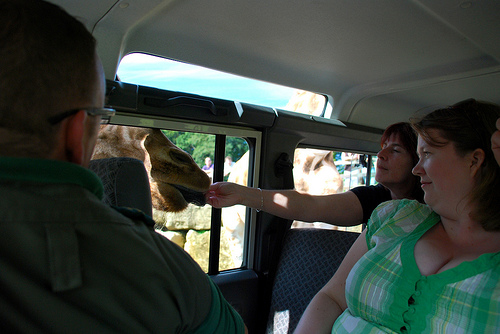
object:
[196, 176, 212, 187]
nose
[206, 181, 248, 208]
hand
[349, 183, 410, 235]
coat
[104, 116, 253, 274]
window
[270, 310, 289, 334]
sun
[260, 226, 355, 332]
seat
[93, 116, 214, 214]
head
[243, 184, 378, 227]
arm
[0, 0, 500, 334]
car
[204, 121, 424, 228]
woman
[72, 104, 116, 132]
eyeglasses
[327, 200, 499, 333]
blouse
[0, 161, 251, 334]
shirt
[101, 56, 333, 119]
sky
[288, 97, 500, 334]
woman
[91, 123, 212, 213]
animal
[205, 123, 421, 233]
people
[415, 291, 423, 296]
buttons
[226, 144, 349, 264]
animal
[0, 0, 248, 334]
man